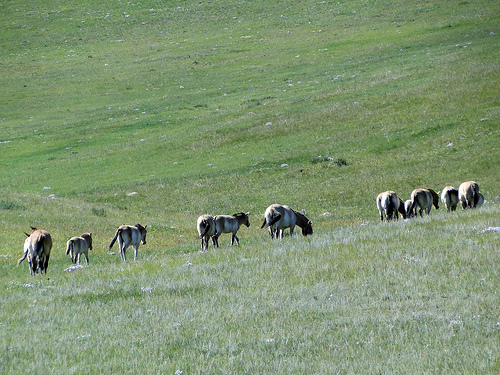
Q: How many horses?
A: 10.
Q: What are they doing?
A: Eating.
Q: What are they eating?
A: Grass.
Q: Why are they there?
A: To eat.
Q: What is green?
A: Grass.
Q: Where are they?
A: Field.